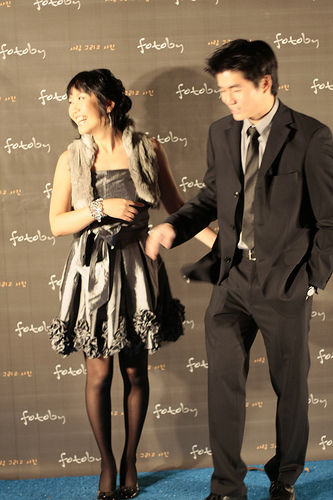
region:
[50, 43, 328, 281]
two people standing together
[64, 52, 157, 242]
a woman with black hair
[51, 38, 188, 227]
a woman with her hair up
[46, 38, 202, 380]
a woman wearing a silver dress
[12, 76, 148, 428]
a woman wearing stockings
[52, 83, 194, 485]
a woman wearing heels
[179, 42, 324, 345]
a man in a suit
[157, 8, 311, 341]
a man wearing a tie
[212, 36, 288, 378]
a man wearing a suit jacket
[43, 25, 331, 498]
they are dressed fancily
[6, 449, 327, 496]
the carpet is blue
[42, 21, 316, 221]
the light shines brightly on them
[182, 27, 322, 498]
he is wearing a suit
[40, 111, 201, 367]
she is wearing a dress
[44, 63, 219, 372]
her dress is silver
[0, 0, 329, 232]
the backdrop is black with red and white text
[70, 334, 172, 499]
she is wearing black stockings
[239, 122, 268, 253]
a black tie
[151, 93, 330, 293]
his jacket is black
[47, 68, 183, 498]
woman wearing sexy hosiery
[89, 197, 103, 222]
a substantial bracelet on a wrist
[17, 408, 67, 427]
the name of a photography studio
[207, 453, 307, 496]
sloppy looking pants legs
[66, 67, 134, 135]
a woman laughing with a man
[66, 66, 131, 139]
woman looking away from her man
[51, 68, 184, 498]
woman wearing nice dress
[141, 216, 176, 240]
man pointing with blurry hand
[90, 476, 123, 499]
right shoe on woman's right foot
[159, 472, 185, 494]
bright blue carpet at an event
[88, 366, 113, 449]
dark black hose on woman's leg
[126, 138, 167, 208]
light brown fur vest on woman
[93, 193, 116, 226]
large chunky braclet on woman's wrist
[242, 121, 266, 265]
dark black tie on man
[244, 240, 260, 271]
silver belt buckle on belt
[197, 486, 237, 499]
dark black man's shoe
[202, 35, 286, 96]
The mans hair is dark.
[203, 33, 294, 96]
The man's hair is black.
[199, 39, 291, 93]
The man's hair is straight.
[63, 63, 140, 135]
The woman's hair is dark.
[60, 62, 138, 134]
The woman's hair is black.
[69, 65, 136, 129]
The woman's hair is straight.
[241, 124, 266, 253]
The man is wearing a necktie.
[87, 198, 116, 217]
The woman is wearing a bracelet.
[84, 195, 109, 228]
The bracelet is sparkling stones.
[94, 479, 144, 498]
The woman is wearing black shoes.